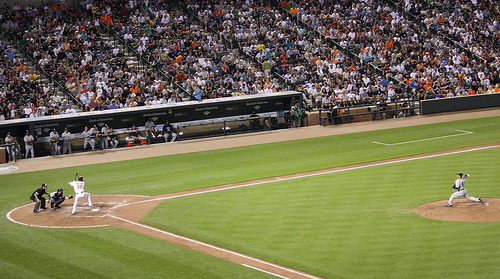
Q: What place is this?
A: It is a stadium.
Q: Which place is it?
A: It is a stadium.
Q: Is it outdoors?
A: Yes, it is outdoors.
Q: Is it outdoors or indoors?
A: It is outdoors.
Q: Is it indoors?
A: No, it is outdoors.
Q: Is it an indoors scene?
A: No, it is outdoors.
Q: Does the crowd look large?
A: Yes, the crowd is large.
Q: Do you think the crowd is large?
A: Yes, the crowd is large.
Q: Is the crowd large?
A: Yes, the crowd is large.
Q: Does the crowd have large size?
A: Yes, the crowd is large.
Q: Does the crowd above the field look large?
A: Yes, the crowd is large.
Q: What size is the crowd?
A: The crowd is large.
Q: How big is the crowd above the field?
A: The crowd is large.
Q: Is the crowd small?
A: No, the crowd is large.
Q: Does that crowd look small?
A: No, the crowd is large.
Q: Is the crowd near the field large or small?
A: The crowd is large.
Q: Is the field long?
A: Yes, the field is long.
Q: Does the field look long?
A: Yes, the field is long.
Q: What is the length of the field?
A: The field is long.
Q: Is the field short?
A: No, the field is long.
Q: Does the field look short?
A: No, the field is long.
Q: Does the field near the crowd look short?
A: No, the field is long.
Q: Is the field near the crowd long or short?
A: The field is long.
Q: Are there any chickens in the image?
A: No, there are no chickens.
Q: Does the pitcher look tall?
A: Yes, the pitcher is tall.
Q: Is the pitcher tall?
A: Yes, the pitcher is tall.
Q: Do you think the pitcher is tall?
A: Yes, the pitcher is tall.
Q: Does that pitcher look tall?
A: Yes, the pitcher is tall.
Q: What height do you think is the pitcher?
A: The pitcher is tall.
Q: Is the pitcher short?
A: No, the pitcher is tall.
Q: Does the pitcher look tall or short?
A: The pitcher is tall.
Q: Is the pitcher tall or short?
A: The pitcher is tall.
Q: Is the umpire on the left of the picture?
A: Yes, the umpire is on the left of the image.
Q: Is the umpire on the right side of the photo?
A: No, the umpire is on the left of the image.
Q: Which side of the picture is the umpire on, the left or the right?
A: The umpire is on the left of the image.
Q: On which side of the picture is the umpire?
A: The umpire is on the left of the image.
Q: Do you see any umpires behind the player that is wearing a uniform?
A: Yes, there is an umpire behind the player.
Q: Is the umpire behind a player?
A: Yes, the umpire is behind a player.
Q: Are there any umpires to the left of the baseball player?
A: Yes, there is an umpire to the left of the player.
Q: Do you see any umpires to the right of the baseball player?
A: No, the umpire is to the left of the player.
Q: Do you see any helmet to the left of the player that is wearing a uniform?
A: No, there is an umpire to the left of the player.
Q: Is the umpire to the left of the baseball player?
A: Yes, the umpire is to the left of the player.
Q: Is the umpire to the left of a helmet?
A: No, the umpire is to the left of the player.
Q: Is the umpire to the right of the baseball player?
A: No, the umpire is to the left of the player.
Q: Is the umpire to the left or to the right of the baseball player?
A: The umpire is to the left of the player.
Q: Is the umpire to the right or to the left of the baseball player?
A: The umpire is to the left of the player.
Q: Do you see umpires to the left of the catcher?
A: Yes, there is an umpire to the left of the catcher.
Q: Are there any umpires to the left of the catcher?
A: Yes, there is an umpire to the left of the catcher.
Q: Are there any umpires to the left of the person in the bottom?
A: Yes, there is an umpire to the left of the catcher.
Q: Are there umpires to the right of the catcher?
A: No, the umpire is to the left of the catcher.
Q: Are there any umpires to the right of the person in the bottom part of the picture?
A: No, the umpire is to the left of the catcher.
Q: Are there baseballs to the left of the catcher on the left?
A: No, there is an umpire to the left of the catcher.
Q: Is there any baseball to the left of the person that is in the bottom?
A: No, there is an umpire to the left of the catcher.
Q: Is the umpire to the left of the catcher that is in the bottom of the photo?
A: Yes, the umpire is to the left of the catcher.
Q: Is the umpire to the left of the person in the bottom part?
A: Yes, the umpire is to the left of the catcher.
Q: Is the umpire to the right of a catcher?
A: No, the umpire is to the left of a catcher.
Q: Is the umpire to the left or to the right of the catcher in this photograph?
A: The umpire is to the left of the catcher.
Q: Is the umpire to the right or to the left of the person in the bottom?
A: The umpire is to the left of the catcher.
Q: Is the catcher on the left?
A: Yes, the catcher is on the left of the image.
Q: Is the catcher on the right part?
A: No, the catcher is on the left of the image.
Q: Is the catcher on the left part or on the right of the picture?
A: The catcher is on the left of the image.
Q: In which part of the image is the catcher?
A: The catcher is on the left of the image.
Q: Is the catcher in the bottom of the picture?
A: Yes, the catcher is in the bottom of the image.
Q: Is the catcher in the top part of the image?
A: No, the catcher is in the bottom of the image.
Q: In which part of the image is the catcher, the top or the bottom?
A: The catcher is in the bottom of the image.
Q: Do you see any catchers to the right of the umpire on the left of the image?
A: Yes, there is a catcher to the right of the umpire.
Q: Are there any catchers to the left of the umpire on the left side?
A: No, the catcher is to the right of the umpire.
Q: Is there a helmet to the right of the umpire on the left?
A: No, there is a catcher to the right of the umpire.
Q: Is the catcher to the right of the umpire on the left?
A: Yes, the catcher is to the right of the umpire.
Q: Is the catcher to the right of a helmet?
A: No, the catcher is to the right of the umpire.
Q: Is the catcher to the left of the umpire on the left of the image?
A: No, the catcher is to the right of the umpire.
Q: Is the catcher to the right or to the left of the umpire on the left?
A: The catcher is to the right of the umpire.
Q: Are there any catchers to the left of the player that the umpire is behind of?
A: Yes, there is a catcher to the left of the player.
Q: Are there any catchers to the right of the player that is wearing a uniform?
A: No, the catcher is to the left of the player.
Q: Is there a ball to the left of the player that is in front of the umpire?
A: No, there is a catcher to the left of the player.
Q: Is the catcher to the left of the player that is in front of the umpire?
A: Yes, the catcher is to the left of the player.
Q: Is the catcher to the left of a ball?
A: No, the catcher is to the left of the player.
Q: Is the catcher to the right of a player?
A: No, the catcher is to the left of a player.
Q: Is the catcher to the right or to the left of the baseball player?
A: The catcher is to the left of the player.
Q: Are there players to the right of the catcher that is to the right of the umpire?
A: Yes, there is a player to the right of the catcher.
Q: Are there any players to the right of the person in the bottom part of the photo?
A: Yes, there is a player to the right of the catcher.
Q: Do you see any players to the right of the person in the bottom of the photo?
A: Yes, there is a player to the right of the catcher.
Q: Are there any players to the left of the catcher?
A: No, the player is to the right of the catcher.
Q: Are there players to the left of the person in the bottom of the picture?
A: No, the player is to the right of the catcher.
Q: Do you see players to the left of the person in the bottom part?
A: No, the player is to the right of the catcher.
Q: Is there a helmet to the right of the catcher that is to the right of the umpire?
A: No, there is a player to the right of the catcher.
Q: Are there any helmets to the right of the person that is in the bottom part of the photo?
A: No, there is a player to the right of the catcher.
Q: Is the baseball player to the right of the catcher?
A: Yes, the player is to the right of the catcher.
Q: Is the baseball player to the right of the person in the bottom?
A: Yes, the player is to the right of the catcher.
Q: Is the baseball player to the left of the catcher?
A: No, the player is to the right of the catcher.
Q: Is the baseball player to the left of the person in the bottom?
A: No, the player is to the right of the catcher.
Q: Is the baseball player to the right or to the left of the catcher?
A: The player is to the right of the catcher.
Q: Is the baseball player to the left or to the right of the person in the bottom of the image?
A: The player is to the right of the catcher.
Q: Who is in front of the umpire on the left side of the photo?
A: The player is in front of the umpire.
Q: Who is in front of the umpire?
A: The player is in front of the umpire.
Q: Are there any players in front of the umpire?
A: Yes, there is a player in front of the umpire.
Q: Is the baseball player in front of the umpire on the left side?
A: Yes, the player is in front of the umpire.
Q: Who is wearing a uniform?
A: The player is wearing a uniform.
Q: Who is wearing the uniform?
A: The player is wearing a uniform.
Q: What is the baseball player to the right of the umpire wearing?
A: The player is wearing a uniform.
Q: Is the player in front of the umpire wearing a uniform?
A: Yes, the player is wearing a uniform.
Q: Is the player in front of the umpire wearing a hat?
A: No, the player is wearing a uniform.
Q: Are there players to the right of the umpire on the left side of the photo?
A: Yes, there is a player to the right of the umpire.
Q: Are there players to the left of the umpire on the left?
A: No, the player is to the right of the umpire.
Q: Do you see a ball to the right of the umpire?
A: No, there is a player to the right of the umpire.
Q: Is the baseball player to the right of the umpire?
A: Yes, the player is to the right of the umpire.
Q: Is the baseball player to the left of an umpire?
A: No, the player is to the right of an umpire.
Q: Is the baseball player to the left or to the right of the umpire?
A: The player is to the right of the umpire.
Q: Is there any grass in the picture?
A: Yes, there is grass.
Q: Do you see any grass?
A: Yes, there is grass.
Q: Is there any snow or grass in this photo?
A: Yes, there is grass.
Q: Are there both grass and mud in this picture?
A: No, there is grass but no mud.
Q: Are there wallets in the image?
A: No, there are no wallets.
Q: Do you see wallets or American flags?
A: No, there are no wallets or American flags.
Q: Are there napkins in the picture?
A: No, there are no napkins.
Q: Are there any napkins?
A: No, there are no napkins.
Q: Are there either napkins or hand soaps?
A: No, there are no napkins or hand soaps.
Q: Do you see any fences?
A: Yes, there is a fence.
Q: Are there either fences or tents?
A: Yes, there is a fence.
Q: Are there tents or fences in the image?
A: Yes, there is a fence.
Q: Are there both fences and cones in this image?
A: No, there is a fence but no cones.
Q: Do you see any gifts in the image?
A: No, there are no gifts.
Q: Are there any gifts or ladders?
A: No, there are no gifts or ladders.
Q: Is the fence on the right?
A: Yes, the fence is on the right of the image.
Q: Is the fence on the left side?
A: No, the fence is on the right of the image.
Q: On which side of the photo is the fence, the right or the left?
A: The fence is on the right of the image.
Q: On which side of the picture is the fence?
A: The fence is on the right of the image.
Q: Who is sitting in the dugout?
A: The players are sitting in the dugout.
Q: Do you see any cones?
A: No, there are no cones.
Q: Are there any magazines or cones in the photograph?
A: No, there are no cones or magazines.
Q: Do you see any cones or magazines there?
A: No, there are no cones or magazines.